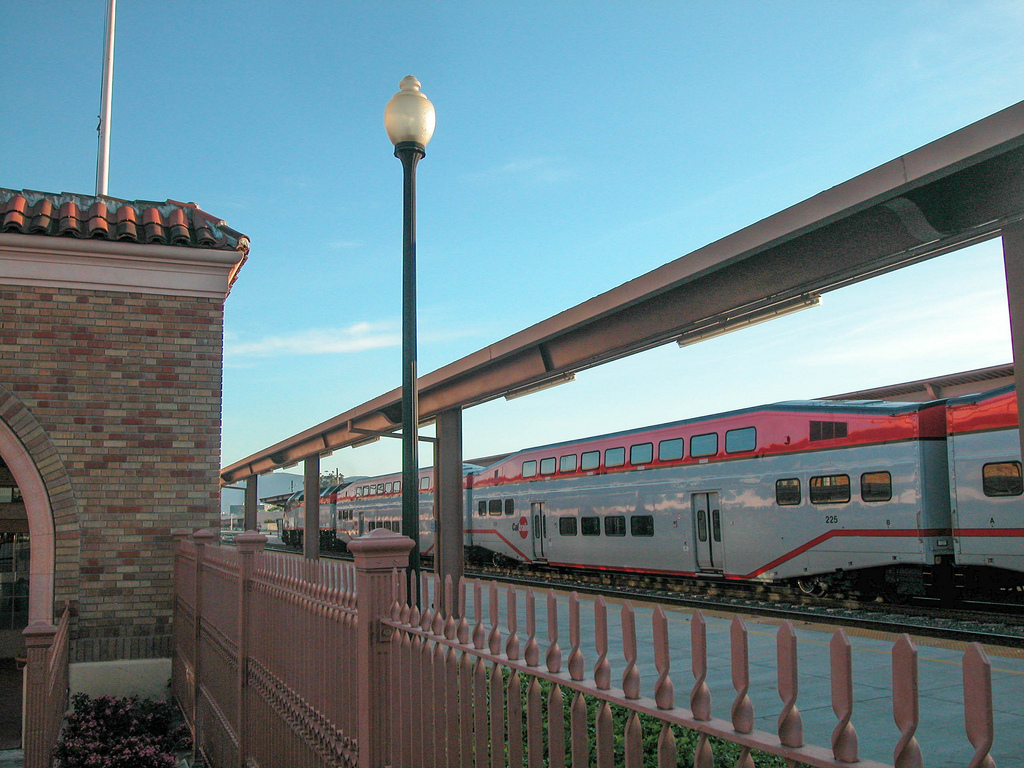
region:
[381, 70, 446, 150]
Street light on the pole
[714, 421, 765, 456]
Window on the train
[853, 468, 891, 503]
Window on the train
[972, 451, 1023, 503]
Window on the train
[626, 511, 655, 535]
Window on the train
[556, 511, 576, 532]
Window on the train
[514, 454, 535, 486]
Window on the train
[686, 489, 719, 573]
Door on the train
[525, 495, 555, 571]
Door on the train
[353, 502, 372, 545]
Door on the train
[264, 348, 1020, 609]
train sitting at the station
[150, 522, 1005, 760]
metal fence painted pink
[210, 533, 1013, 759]
cement waiting platform at train station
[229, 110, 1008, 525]
awning to protect from weather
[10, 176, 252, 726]
brick building with pink trim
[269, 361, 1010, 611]
passenger train painted white and red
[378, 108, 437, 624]
black metal light pole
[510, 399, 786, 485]
windows on the very top of a train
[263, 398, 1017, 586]
gray and red train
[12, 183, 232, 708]
brick building next to the train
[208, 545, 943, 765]
platform beside the train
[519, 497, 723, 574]
doors on the train cars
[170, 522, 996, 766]
brown railing beside the platform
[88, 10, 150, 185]
pole behind the brick building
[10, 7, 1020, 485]
blue sky with one cloud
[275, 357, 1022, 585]
silver and red shiny train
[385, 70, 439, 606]
tall black pole with lamp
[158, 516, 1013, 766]
brown wooden fence near walkway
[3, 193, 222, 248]
red clay bricks atop building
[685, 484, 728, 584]
double doors on side of train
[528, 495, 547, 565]
double doors on side of train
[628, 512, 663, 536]
window on side of train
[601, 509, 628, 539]
window on side of train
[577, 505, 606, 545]
window on side of train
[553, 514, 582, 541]
window on side of train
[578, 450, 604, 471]
train has a window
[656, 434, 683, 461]
train has a window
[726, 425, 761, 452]
train has a window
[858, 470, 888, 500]
train has a window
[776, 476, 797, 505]
train has a window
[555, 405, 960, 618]
a train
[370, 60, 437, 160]
a street light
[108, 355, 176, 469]
a brick building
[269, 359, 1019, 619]
A long gray and red train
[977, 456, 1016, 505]
a window on a train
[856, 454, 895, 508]
a window on a train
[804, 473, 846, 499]
a window on a train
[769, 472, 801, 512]
a window on a train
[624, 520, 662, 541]
a window on a train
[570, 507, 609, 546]
a window on a train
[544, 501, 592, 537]
a window on a train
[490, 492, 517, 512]
a window on a train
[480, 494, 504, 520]
a window on a train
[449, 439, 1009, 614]
this is a train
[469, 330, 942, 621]
this is a passenger train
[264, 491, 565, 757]
the fence is metal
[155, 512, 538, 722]
the fence is pink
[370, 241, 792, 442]
the overhang is metal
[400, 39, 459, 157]
the bulb is white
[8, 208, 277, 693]
the buliding is brick